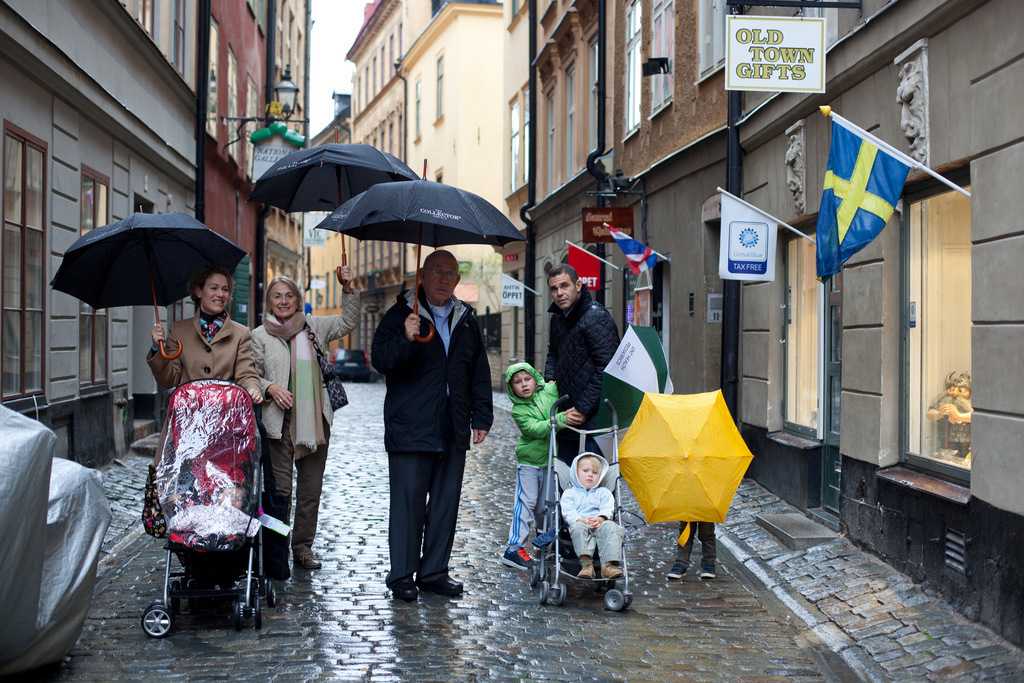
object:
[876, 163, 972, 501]
window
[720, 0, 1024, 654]
building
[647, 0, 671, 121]
window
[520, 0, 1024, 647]
building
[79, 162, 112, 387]
window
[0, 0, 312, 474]
building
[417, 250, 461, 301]
head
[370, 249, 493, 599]
man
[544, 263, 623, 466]
man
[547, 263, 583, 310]
head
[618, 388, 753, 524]
umbrella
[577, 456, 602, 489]
head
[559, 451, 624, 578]
boy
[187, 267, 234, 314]
head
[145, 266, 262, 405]
woman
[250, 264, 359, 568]
woman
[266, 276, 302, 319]
head